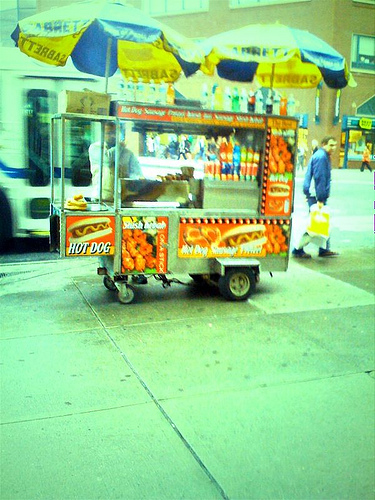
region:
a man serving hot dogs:
[89, 126, 143, 190]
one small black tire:
[202, 262, 256, 301]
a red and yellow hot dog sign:
[62, 216, 128, 255]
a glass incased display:
[54, 113, 115, 210]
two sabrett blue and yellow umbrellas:
[2, 34, 356, 116]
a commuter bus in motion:
[0, 94, 51, 282]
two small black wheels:
[102, 267, 148, 313]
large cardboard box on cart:
[62, 84, 129, 121]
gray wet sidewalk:
[82, 320, 313, 459]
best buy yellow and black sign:
[344, 114, 370, 139]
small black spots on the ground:
[70, 358, 197, 397]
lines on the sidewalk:
[63, 295, 276, 357]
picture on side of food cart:
[70, 214, 130, 248]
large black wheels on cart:
[223, 269, 283, 317]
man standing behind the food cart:
[92, 112, 142, 205]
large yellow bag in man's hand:
[298, 197, 348, 254]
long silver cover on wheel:
[197, 248, 284, 281]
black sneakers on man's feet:
[293, 241, 348, 262]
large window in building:
[340, 17, 373, 88]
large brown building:
[231, 4, 371, 74]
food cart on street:
[45, 108, 283, 318]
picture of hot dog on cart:
[217, 218, 273, 252]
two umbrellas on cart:
[23, 27, 363, 82]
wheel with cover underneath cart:
[211, 254, 262, 304]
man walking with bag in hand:
[295, 131, 339, 264]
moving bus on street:
[9, 60, 93, 229]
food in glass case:
[61, 193, 94, 215]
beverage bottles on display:
[198, 135, 261, 183]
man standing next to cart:
[86, 116, 149, 214]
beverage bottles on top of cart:
[108, 75, 296, 115]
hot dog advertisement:
[61, 211, 115, 256]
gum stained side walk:
[65, 327, 285, 457]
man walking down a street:
[290, 124, 337, 274]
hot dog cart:
[39, 101, 296, 316]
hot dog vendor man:
[87, 106, 146, 222]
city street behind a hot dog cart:
[0, 6, 370, 288]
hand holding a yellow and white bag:
[302, 188, 328, 247]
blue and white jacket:
[304, 137, 334, 209]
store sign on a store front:
[333, 98, 373, 168]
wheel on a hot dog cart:
[207, 253, 264, 309]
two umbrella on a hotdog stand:
[17, 11, 345, 122]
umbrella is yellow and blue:
[12, 2, 204, 99]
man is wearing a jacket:
[299, 144, 343, 210]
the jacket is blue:
[301, 146, 341, 196]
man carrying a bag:
[302, 154, 325, 243]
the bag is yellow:
[299, 182, 342, 245]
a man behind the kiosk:
[90, 117, 169, 225]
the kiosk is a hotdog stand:
[86, 123, 321, 309]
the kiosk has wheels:
[95, 249, 272, 325]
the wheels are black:
[206, 271, 284, 308]